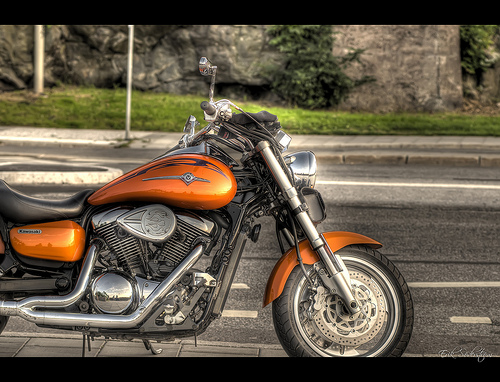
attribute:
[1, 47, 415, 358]
motorcycle — orange, parked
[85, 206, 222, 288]
engine — v twin, silver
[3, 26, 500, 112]
wall — background, brown, heavy, gray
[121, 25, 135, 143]
pole — metal, gray, white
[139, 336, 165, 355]
kickstand — down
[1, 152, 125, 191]
island — concrete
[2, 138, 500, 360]
street — gray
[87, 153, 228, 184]
marks — black, tribal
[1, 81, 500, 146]
grass — green, background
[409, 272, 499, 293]
line — white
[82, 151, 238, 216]
tank — orange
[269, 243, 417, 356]
wheel — black, roudn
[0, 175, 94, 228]
seat — leather, black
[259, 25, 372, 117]
tree — background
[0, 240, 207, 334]
pipes — silver, chrome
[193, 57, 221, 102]
mirror — metal